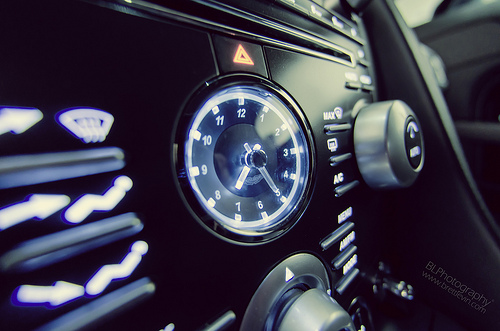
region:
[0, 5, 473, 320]
black clean board truck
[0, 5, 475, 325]
board truck with lights on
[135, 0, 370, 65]
CD player in black board truck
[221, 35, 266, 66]
flashing lights button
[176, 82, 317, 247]
speedometer with lights on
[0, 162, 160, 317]
air conditioner buttons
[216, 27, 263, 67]
buton with orange triangle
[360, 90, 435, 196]
small wheel in the right side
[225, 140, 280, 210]
small hands of speedometer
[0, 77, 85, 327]
three arrow lights on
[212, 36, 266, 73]
the hazard light is lit up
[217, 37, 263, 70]
the symbol is reddish orange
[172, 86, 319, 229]
the clock light is on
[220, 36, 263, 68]
the hazard sign is a triangle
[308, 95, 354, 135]
max button for the air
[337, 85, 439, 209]
a big knob to the right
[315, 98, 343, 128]
the letters are white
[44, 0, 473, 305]
the dash board in a car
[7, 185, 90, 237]
arrow pointing to the right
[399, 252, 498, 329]
photographer information on the bottom right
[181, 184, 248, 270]
interior of a saloon car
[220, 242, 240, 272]
part of a watch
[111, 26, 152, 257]
part of a stereo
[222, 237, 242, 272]
part of a button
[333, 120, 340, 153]
edge of a button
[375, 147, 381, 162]
edge of a button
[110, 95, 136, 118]
part of a start button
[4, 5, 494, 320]
A vehicle dashboard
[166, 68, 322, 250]
A clock is in the dash board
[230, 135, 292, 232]
The time is 7:25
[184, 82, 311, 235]
The clock face is illuminated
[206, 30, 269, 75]
The caution light button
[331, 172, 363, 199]
The air conditioning indicator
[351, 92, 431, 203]
A control knob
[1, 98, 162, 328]
The car air vent controls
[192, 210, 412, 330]
The stereo controls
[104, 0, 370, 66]
A CD slot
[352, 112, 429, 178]
a knob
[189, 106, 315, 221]
a clock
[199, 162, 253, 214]
numbers on the clock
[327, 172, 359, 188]
the writing AC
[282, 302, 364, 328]
the knob is grey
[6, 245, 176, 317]
a sign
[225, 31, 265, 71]
a triangle thats orange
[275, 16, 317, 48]
a cd player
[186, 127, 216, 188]
the numbers are white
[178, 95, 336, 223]
the clock is small